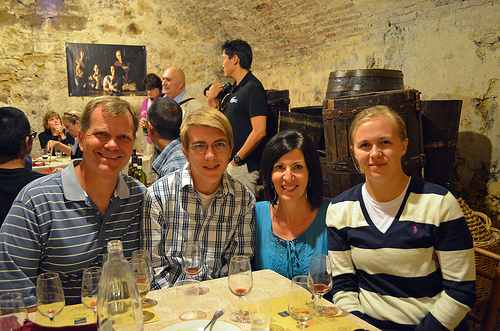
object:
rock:
[228, 256, 254, 323]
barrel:
[323, 70, 426, 199]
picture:
[65, 42, 146, 97]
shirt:
[0, 167, 48, 224]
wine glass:
[36, 272, 66, 326]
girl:
[325, 104, 476, 329]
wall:
[2, 0, 234, 159]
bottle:
[96, 240, 144, 330]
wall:
[0, 1, 496, 225]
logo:
[413, 224, 419, 234]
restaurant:
[0, 0, 500, 331]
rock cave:
[0, 3, 500, 331]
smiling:
[97, 151, 124, 160]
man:
[47, 109, 83, 159]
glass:
[306, 254, 332, 316]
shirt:
[0, 157, 148, 312]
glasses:
[188, 144, 230, 153]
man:
[0, 107, 49, 227]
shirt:
[218, 70, 268, 173]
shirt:
[140, 162, 256, 291]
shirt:
[326, 176, 478, 331]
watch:
[234, 155, 242, 165]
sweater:
[255, 196, 331, 288]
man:
[206, 38, 267, 196]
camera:
[204, 81, 236, 102]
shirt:
[253, 196, 329, 287]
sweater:
[325, 175, 477, 331]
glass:
[228, 256, 254, 323]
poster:
[65, 42, 147, 95]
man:
[146, 97, 188, 181]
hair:
[178, 107, 234, 149]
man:
[0, 96, 147, 313]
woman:
[254, 129, 335, 291]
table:
[3, 269, 383, 331]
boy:
[139, 107, 256, 290]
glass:
[288, 275, 317, 330]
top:
[106, 232, 124, 255]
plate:
[158, 319, 247, 330]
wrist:
[233, 154, 244, 163]